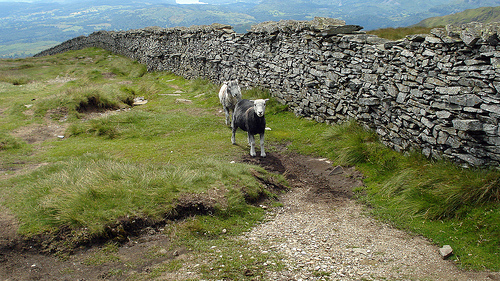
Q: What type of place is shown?
A: It is a path.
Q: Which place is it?
A: It is a path.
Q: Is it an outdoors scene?
A: Yes, it is outdoors.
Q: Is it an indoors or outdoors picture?
A: It is outdoors.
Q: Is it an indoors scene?
A: No, it is outdoors.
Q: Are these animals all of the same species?
A: No, there are both sheep and goats.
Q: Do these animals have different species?
A: Yes, they are sheep and goats.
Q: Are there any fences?
A: Yes, there is a fence.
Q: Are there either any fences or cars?
A: Yes, there is a fence.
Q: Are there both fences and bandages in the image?
A: No, there is a fence but no bandages.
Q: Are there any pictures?
A: No, there are no pictures.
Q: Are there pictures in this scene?
A: No, there are no pictures.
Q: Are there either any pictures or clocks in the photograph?
A: No, there are no pictures or clocks.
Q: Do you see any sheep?
A: Yes, there is a sheep.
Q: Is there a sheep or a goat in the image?
A: Yes, there is a sheep.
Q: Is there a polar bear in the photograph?
A: No, there are no polar bears.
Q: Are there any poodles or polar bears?
A: No, there are no polar bears or poodles.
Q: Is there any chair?
A: No, there are no chairs.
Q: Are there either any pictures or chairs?
A: No, there are no chairs or pictures.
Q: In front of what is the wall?
A: The wall is in front of the hills.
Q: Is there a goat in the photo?
A: Yes, there is a goat.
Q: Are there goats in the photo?
A: Yes, there is a goat.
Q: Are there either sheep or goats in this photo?
A: Yes, there is a goat.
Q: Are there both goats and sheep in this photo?
A: Yes, there are both a goat and a sheep.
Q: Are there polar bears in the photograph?
A: No, there are no polar bears.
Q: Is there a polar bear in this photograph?
A: No, there are no polar bears.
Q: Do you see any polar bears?
A: No, there are no polar bears.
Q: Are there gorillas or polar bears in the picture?
A: No, there are no polar bears or gorillas.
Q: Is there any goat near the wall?
A: Yes, there is a goat near the wall.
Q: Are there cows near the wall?
A: No, there is a goat near the wall.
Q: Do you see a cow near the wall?
A: No, there is a goat near the wall.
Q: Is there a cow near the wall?
A: No, there is a goat near the wall.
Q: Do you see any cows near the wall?
A: No, there is a goat near the wall.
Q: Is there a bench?
A: No, there are no benches.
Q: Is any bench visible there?
A: No, there are no benches.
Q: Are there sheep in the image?
A: Yes, there is a sheep.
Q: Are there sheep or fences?
A: Yes, there is a sheep.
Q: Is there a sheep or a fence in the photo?
A: Yes, there is a sheep.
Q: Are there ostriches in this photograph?
A: No, there are no ostriches.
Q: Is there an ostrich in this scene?
A: No, there are no ostriches.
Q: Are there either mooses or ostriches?
A: No, there are no ostriches or mooses.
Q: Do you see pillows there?
A: No, there are no pillows.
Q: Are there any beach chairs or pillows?
A: No, there are no pillows or beach chairs.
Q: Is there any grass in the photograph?
A: Yes, there is grass.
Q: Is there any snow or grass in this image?
A: Yes, there is grass.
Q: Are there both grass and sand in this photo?
A: No, there is grass but no sand.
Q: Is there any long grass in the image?
A: Yes, there is long grass.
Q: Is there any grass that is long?
A: Yes, there is long grass.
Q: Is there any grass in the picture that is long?
A: Yes, there is grass that is long.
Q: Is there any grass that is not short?
A: Yes, there is long grass.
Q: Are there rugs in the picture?
A: No, there are no rugs.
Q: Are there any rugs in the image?
A: No, there are no rugs.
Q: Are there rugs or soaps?
A: No, there are no rugs or soaps.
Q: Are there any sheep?
A: Yes, there is a sheep.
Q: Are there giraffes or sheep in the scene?
A: Yes, there is a sheep.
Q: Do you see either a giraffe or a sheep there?
A: Yes, there is a sheep.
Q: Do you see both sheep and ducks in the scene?
A: No, there is a sheep but no ducks.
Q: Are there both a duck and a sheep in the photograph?
A: No, there is a sheep but no ducks.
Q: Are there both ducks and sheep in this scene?
A: No, there is a sheep but no ducks.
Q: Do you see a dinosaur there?
A: No, there are no dinosaurs.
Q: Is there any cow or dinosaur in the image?
A: No, there are no dinosaurs or cows.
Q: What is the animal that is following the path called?
A: The animal is a sheep.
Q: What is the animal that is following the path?
A: The animal is a sheep.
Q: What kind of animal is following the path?
A: The animal is a sheep.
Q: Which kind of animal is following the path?
A: The animal is a sheep.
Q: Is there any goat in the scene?
A: Yes, there is a goat.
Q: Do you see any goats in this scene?
A: Yes, there is a goat.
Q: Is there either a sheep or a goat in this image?
A: Yes, there is a goat.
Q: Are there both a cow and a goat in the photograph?
A: No, there is a goat but no cows.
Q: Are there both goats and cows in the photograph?
A: No, there is a goat but no cows.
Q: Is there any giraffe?
A: No, there are no giraffes.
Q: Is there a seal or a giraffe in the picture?
A: No, there are no giraffes or seals.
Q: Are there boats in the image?
A: No, there are no boats.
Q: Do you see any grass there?
A: Yes, there is grass.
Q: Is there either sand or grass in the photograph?
A: Yes, there is grass.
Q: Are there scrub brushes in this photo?
A: No, there are no scrub brushes.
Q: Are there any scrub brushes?
A: No, there are no scrub brushes.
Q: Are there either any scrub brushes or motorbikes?
A: No, there are no scrub brushes or motorbikes.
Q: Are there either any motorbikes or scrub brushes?
A: No, there are no scrub brushes or motorbikes.